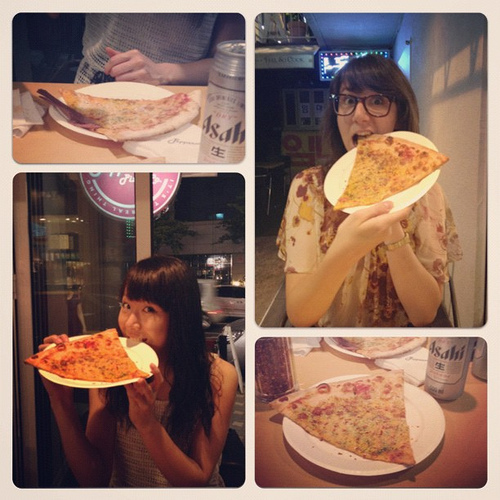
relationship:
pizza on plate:
[360, 145, 402, 187] [327, 165, 345, 189]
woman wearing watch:
[337, 91, 421, 320] [393, 240, 415, 256]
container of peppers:
[260, 347, 289, 394] [270, 373, 284, 384]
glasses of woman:
[336, 90, 402, 122] [337, 91, 421, 320]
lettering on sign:
[95, 201, 127, 216] [46, 149, 179, 225]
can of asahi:
[427, 344, 482, 408] [427, 343, 464, 358]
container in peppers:
[260, 347, 289, 394] [270, 373, 284, 384]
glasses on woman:
[336, 90, 402, 122] [337, 91, 421, 320]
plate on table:
[327, 165, 345, 189] [29, 136, 75, 150]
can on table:
[427, 344, 482, 408] [29, 136, 75, 150]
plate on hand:
[327, 165, 345, 189] [342, 214, 396, 244]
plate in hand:
[327, 165, 345, 189] [342, 214, 396, 244]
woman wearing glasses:
[337, 91, 421, 320] [336, 90, 402, 122]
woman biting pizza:
[337, 91, 421, 320] [360, 145, 402, 187]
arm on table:
[131, 60, 225, 83] [29, 136, 75, 150]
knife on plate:
[43, 93, 79, 117] [327, 165, 345, 189]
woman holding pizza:
[337, 91, 421, 320] [360, 145, 402, 187]